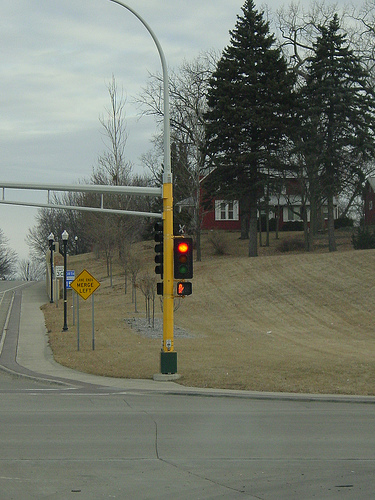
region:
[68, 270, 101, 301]
Sign stating "lane ends merge left"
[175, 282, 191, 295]
Don't walk sign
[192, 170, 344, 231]
red house in background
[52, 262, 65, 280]
speed limit sign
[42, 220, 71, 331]
two streetlamps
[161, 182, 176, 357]
yellow traffic light pole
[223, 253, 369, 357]
empty brown hill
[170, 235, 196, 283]
traffic light showing a red light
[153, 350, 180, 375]
black base of yellow pole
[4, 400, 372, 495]
gray street in foreground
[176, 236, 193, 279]
A row of three traffic lights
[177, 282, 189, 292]
a glowing red pedestrian light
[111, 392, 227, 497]
a winding crack in the road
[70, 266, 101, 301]
a diamond shaped merge sign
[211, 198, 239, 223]
a white window on a house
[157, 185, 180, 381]
a yellow metal street light pole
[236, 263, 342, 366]
a slope with brown grass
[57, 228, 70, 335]
a black and white street light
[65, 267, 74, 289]
a blue and white sign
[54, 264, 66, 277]
a black and white speed limit sign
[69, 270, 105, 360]
merge left street sign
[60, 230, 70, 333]
black iron light post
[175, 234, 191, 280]
black electronic street light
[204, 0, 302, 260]
large evergreen tree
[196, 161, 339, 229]
red and white house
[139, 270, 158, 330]
small tree bare sapling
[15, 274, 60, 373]
concrete sidewalk next to street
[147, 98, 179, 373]
yellow and grey pole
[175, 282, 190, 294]
electronic don't walk sign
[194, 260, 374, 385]
brown dried grass yard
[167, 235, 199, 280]
red stop light lit up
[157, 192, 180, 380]
yellow and green traffic light pole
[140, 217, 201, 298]
traffic lights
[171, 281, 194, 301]
cross walk sign with red hand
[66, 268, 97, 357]
street sign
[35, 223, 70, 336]
old fashioned looking street lights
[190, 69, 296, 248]
large green trees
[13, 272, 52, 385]
side walk on the side of the road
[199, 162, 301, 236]
red house in the background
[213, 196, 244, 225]
windows with white window outline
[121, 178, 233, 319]
the traffic light is in red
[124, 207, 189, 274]
the traffic light is in red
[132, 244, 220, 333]
the traffic light is in red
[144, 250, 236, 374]
the traffic light is in red